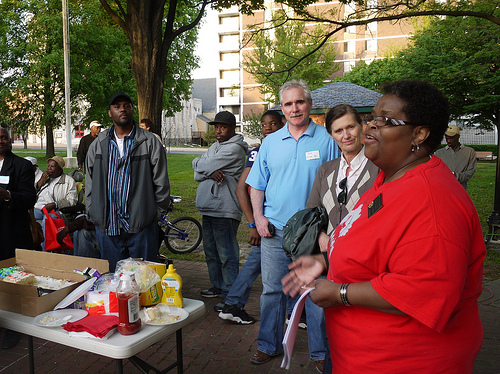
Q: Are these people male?
A: No, they are both male and female.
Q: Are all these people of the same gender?
A: No, they are both male and female.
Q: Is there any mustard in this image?
A: Yes, there is mustard.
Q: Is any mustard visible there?
A: Yes, there is mustard.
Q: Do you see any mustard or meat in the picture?
A: Yes, there is mustard.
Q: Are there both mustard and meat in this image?
A: No, there is mustard but no meat.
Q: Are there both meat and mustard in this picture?
A: No, there is mustard but no meat.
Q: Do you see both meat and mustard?
A: No, there is mustard but no meat.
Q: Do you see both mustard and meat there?
A: No, there is mustard but no meat.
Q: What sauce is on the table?
A: The sauce is mustard.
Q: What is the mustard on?
A: The mustard is on the table.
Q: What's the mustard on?
A: The mustard is on the table.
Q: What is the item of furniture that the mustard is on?
A: The piece of furniture is a table.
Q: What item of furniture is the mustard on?
A: The mustard is on the table.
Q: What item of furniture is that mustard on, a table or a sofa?
A: The mustard is on a table.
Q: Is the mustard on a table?
A: Yes, the mustard is on a table.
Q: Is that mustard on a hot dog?
A: No, the mustard is on a table.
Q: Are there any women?
A: Yes, there is a woman.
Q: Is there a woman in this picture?
A: Yes, there is a woman.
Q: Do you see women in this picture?
A: Yes, there is a woman.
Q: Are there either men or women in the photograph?
A: Yes, there is a woman.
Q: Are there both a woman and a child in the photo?
A: No, there is a woman but no children.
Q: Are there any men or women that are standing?
A: Yes, the woman is standing.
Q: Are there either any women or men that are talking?
A: Yes, the woman is talking.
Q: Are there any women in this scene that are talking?
A: Yes, there is a woman that is talking.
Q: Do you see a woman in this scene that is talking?
A: Yes, there is a woman that is talking.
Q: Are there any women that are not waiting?
A: Yes, there is a woman that is talking.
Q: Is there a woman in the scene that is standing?
A: Yes, there is a woman that is standing.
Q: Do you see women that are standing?
A: Yes, there is a woman that is standing.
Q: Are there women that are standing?
A: Yes, there is a woman that is standing.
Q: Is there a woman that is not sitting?
A: Yes, there is a woman that is standing.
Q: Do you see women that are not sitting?
A: Yes, there is a woman that is standing .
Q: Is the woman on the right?
A: Yes, the woman is on the right of the image.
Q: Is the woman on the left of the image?
A: No, the woman is on the right of the image.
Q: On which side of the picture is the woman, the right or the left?
A: The woman is on the right of the image.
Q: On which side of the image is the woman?
A: The woman is on the right of the image.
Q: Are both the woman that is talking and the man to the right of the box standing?
A: Yes, both the woman and the man are standing.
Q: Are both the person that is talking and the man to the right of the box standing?
A: Yes, both the woman and the man are standing.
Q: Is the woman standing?
A: Yes, the woman is standing.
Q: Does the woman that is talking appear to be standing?
A: Yes, the woman is standing.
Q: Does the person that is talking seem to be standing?
A: Yes, the woman is standing.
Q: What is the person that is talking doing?
A: The woman is standing.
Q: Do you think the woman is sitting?
A: No, the woman is standing.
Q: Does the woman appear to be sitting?
A: No, the woman is standing.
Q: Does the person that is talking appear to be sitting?
A: No, the woman is standing.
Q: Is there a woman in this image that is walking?
A: No, there is a woman but she is standing.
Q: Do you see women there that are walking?
A: No, there is a woman but she is standing.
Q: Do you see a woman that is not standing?
A: No, there is a woman but she is standing.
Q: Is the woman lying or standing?
A: The woman is standing.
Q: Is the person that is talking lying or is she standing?
A: The woman is standing.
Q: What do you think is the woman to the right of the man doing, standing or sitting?
A: The woman is standing.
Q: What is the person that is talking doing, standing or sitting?
A: The woman is standing.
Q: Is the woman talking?
A: Yes, the woman is talking.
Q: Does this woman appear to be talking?
A: Yes, the woman is talking.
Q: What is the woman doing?
A: The woman is talking.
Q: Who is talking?
A: The woman is talking.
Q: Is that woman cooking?
A: No, the woman is talking.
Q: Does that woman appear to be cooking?
A: No, the woman is talking.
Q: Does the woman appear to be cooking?
A: No, the woman is talking.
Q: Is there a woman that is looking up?
A: No, there is a woman but she is talking.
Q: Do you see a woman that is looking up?
A: No, there is a woman but she is talking.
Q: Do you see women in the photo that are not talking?
A: No, there is a woman but she is talking.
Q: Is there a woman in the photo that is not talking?
A: No, there is a woman but she is talking.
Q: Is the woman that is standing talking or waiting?
A: The woman is talking.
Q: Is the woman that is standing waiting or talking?
A: The woman is talking.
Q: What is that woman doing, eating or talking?
A: The woman is talking.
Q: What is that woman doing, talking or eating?
A: The woman is talking.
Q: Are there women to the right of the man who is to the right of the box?
A: Yes, there is a woman to the right of the man.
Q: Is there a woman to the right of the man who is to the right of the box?
A: Yes, there is a woman to the right of the man.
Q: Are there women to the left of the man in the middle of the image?
A: No, the woman is to the right of the man.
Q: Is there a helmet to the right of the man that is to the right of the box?
A: No, there is a woman to the right of the man.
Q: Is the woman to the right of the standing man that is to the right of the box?
A: Yes, the woman is to the right of the man.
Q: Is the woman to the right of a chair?
A: No, the woman is to the right of the man.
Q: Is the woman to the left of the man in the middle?
A: No, the woman is to the right of the man.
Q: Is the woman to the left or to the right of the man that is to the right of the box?
A: The woman is to the right of the man.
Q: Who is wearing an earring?
A: The woman is wearing an earring.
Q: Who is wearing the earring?
A: The woman is wearing an earring.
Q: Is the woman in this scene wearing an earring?
A: Yes, the woman is wearing an earring.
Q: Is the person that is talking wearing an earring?
A: Yes, the woman is wearing an earring.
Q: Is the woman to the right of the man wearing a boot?
A: No, the woman is wearing an earring.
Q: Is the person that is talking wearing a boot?
A: No, the woman is wearing an earring.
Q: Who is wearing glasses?
A: The woman is wearing glasses.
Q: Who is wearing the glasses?
A: The woman is wearing glasses.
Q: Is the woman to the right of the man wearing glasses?
A: Yes, the woman is wearing glasses.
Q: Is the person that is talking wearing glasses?
A: Yes, the woman is wearing glasses.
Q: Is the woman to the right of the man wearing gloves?
A: No, the woman is wearing glasses.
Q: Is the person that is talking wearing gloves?
A: No, the woman is wearing glasses.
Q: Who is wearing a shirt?
A: The woman is wearing a shirt.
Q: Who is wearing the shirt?
A: The woman is wearing a shirt.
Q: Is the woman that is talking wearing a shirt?
A: Yes, the woman is wearing a shirt.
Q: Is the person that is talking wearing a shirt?
A: Yes, the woman is wearing a shirt.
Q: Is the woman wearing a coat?
A: No, the woman is wearing a shirt.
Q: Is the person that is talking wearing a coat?
A: No, the woman is wearing a shirt.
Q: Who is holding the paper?
A: The woman is holding the paper.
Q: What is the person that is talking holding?
A: The woman is holding the paper.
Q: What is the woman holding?
A: The woman is holding the paper.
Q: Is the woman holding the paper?
A: Yes, the woman is holding the paper.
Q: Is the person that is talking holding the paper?
A: Yes, the woman is holding the paper.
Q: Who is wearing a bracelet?
A: The woman is wearing a bracelet.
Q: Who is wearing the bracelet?
A: The woman is wearing a bracelet.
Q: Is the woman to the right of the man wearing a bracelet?
A: Yes, the woman is wearing a bracelet.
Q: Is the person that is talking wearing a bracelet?
A: Yes, the woman is wearing a bracelet.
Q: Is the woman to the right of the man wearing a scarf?
A: No, the woman is wearing a bracelet.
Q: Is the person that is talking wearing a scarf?
A: No, the woman is wearing a bracelet.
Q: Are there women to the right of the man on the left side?
A: Yes, there is a woman to the right of the man.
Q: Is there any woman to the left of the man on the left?
A: No, the woman is to the right of the man.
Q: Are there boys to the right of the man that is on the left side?
A: No, there is a woman to the right of the man.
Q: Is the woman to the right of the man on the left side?
A: Yes, the woman is to the right of the man.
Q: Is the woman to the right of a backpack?
A: No, the woman is to the right of the man.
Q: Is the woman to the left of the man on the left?
A: No, the woman is to the right of the man.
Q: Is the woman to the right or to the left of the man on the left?
A: The woman is to the right of the man.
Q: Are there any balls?
A: No, there are no balls.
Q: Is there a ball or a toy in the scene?
A: No, there are no balls or toys.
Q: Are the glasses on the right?
A: Yes, the glasses are on the right of the image.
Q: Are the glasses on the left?
A: No, the glasses are on the right of the image.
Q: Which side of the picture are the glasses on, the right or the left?
A: The glasses are on the right of the image.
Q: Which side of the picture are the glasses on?
A: The glasses are on the right of the image.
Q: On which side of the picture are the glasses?
A: The glasses are on the right of the image.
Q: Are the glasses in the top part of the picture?
A: Yes, the glasses are in the top of the image.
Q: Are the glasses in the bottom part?
A: No, the glasses are in the top of the image.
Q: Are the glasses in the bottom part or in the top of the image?
A: The glasses are in the top of the image.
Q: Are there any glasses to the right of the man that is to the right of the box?
A: Yes, there are glasses to the right of the man.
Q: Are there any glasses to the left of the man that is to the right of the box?
A: No, the glasses are to the right of the man.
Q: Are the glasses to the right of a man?
A: Yes, the glasses are to the right of a man.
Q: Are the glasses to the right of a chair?
A: No, the glasses are to the right of a man.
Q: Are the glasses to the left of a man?
A: No, the glasses are to the right of a man.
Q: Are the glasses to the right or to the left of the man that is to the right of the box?
A: The glasses are to the right of the man.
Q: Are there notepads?
A: No, there are no notepads.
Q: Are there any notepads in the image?
A: No, there are no notepads.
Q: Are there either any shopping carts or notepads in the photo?
A: No, there are no notepads or shopping carts.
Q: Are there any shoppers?
A: No, there are no shoppers.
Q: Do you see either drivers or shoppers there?
A: No, there are no shoppers or drivers.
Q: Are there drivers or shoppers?
A: No, there are no shoppers or drivers.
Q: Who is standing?
A: The man is standing.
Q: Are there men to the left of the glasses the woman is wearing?
A: Yes, there is a man to the left of the glasses.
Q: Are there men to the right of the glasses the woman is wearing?
A: No, the man is to the left of the glasses.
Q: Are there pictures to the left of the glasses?
A: No, there is a man to the left of the glasses.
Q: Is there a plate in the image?
A: Yes, there is a plate.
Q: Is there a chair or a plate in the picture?
A: Yes, there is a plate.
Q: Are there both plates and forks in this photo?
A: No, there is a plate but no forks.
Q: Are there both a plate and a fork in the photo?
A: No, there is a plate but no forks.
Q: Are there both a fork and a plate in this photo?
A: No, there is a plate but no forks.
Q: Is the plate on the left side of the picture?
A: Yes, the plate is on the left of the image.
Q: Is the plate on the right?
A: No, the plate is on the left of the image.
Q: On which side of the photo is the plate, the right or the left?
A: The plate is on the left of the image.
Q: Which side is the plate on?
A: The plate is on the left of the image.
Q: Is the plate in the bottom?
A: Yes, the plate is in the bottom of the image.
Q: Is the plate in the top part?
A: No, the plate is in the bottom of the image.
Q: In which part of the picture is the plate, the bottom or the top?
A: The plate is in the bottom of the image.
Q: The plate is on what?
A: The plate is on the table.